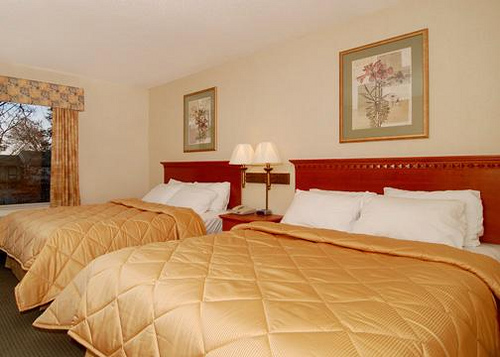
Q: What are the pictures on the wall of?
A: The pictures are of flowers.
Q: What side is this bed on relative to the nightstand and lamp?
A: The bed is on the right side of the lamp.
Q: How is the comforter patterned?
A: A solid colored quilt pattern.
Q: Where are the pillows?
A: On bed.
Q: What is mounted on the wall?
A: Pictures.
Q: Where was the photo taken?
A: In hotel room.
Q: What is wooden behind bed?
A: Headboard.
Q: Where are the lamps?
A: On side table.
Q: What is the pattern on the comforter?
A: Quilted.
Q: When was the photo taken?
A: In the daytime.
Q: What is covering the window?
A: Curtains.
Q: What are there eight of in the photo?
A: Pillows.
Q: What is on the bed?
A: Gold comforters.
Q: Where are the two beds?
A: In a hotel room.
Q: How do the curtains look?
A: They are light beige in color.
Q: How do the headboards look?
A: They are cherry stained.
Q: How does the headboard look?
A: The headboard is red.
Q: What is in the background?
A: Gold curtains.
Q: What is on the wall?
A: Two pictures.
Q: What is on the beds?
A: Four pillows.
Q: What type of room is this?
A: Hotel.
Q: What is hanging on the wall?
A: Picture.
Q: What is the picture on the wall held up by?
A: Frame.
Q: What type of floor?
A: Carpet.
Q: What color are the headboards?
A: Red.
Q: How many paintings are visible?
A: Two.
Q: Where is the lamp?
A: On the table.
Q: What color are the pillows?
A: White.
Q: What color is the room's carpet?
A: Green.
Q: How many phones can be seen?
A: One.